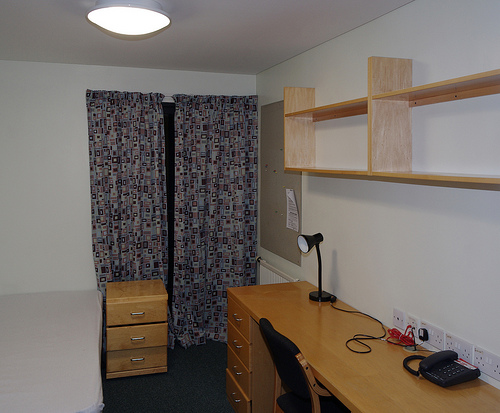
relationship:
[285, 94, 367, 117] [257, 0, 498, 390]
shelf hung on wall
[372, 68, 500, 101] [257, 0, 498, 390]
shelf hung on wall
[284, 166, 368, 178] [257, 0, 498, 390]
shelf hung on wall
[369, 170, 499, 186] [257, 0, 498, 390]
shelf hung on wall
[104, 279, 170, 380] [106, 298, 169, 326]
dresser has drawer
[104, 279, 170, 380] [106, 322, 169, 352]
dresser has drawer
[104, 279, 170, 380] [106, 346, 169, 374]
dresser has drawer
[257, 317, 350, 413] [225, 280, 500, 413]
chair pushed under desk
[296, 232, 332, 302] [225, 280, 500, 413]
lamp on top of desk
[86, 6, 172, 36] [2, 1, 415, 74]
light on ceiling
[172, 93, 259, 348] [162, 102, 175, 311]
curtain covering window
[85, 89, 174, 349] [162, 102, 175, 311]
curtain covering window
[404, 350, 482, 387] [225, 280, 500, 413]
telephone on top of desk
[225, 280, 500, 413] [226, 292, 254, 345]
desk has drawer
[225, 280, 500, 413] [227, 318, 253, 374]
desk has drawer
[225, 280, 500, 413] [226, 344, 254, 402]
desk has drawer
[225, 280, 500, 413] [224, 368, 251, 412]
desk has drawer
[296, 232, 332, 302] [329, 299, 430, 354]
lamp has cord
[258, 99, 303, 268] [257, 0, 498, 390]
bulletin board hanging on wall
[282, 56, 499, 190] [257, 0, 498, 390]
shelf set on wall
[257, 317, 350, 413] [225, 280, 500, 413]
chair underneath desk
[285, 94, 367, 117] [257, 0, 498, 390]
shelf attached to wall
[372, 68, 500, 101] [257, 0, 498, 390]
shelf attached to wall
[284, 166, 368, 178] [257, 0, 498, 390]
shelf attached to wall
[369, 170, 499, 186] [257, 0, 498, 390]
shelf attached to wall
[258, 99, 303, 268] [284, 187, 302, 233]
bulletin board has paper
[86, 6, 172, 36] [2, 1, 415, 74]
light hanging from ceiling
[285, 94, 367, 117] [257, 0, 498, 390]
shelf hanging on wall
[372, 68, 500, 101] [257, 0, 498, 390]
shelf hanging on wall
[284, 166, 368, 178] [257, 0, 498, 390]
shelf hanging on wall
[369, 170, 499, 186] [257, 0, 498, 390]
shelf hanging on wall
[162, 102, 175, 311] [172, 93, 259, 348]
window has curtain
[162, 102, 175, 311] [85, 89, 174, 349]
window has curtain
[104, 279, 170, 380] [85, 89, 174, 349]
dresser in front of curtain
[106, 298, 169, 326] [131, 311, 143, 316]
drawer has drawer pull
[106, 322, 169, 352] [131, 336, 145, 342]
drawer has drawer pull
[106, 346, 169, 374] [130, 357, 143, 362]
drawer has drawer pull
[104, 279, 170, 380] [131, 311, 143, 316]
dresser has drawer pull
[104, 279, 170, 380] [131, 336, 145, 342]
dresser has drawer pull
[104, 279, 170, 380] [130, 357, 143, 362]
dresser has drawer pull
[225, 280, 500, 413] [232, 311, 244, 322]
desk has handle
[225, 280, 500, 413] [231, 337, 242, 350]
desk has handle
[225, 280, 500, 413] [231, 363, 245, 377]
desk has handle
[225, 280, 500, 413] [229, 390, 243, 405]
desk has handle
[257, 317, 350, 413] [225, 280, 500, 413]
chair pushed up to desk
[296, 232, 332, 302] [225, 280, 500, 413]
lamp sitting on desk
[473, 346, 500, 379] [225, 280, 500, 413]
electrical outlet above desk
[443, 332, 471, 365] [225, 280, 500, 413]
electrical outlet above desk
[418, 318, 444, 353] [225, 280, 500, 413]
electrical outlet above desk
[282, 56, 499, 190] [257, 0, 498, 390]
shelf set hanging on wall